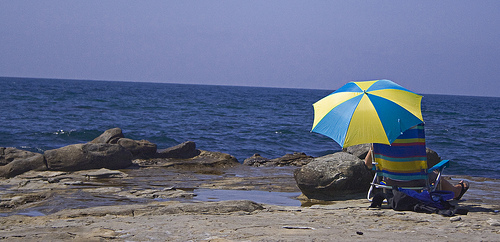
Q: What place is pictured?
A: It is a beach.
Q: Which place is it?
A: It is a beach.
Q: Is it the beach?
A: Yes, it is the beach.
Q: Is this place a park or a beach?
A: It is a beach.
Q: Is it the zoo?
A: No, it is the beach.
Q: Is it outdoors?
A: Yes, it is outdoors.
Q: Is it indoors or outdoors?
A: It is outdoors.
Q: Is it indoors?
A: No, it is outdoors.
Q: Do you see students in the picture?
A: No, there are no students.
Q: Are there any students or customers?
A: No, there are no students or customers.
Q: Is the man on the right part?
A: Yes, the man is on the right of the image.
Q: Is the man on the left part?
A: No, the man is on the right of the image.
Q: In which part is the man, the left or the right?
A: The man is on the right of the image.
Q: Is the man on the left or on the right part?
A: The man is on the right of the image.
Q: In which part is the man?
A: The man is on the right of the image.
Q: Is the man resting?
A: Yes, the man is resting.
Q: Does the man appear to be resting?
A: Yes, the man is resting.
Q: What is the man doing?
A: The man is resting.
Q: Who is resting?
A: The man is resting.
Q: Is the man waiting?
A: No, the man is resting.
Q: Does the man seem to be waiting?
A: No, the man is resting.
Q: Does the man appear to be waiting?
A: No, the man is resting.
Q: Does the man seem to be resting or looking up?
A: The man is resting.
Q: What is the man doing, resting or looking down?
A: The man is resting.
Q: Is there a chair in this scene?
A: Yes, there is a chair.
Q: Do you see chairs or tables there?
A: Yes, there is a chair.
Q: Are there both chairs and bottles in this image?
A: No, there is a chair but no bottles.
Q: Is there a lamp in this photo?
A: No, there are no lamps.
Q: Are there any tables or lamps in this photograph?
A: No, there are no lamps or tables.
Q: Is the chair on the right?
A: Yes, the chair is on the right of the image.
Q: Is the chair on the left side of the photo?
A: No, the chair is on the right of the image.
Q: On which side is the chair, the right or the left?
A: The chair is on the right of the image.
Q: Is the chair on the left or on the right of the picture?
A: The chair is on the right of the image.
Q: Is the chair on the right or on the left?
A: The chair is on the right of the image.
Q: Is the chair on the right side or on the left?
A: The chair is on the right of the image.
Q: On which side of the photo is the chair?
A: The chair is on the right of the image.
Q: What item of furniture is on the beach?
A: The piece of furniture is a chair.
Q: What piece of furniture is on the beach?
A: The piece of furniture is a chair.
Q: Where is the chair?
A: The chair is on the beach.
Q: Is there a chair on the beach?
A: Yes, there is a chair on the beach.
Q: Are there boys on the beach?
A: No, there is a chair on the beach.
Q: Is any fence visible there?
A: No, there are no fences.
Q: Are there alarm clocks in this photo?
A: No, there are no alarm clocks.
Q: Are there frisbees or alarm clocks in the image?
A: No, there are no alarm clocks or frisbees.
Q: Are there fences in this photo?
A: No, there are no fences.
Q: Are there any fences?
A: No, there are no fences.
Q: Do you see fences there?
A: No, there are no fences.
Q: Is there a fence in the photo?
A: No, there are no fences.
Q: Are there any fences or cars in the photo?
A: No, there are no fences or cars.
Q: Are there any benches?
A: No, there are no benches.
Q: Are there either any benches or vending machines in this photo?
A: No, there are no benches or vending machines.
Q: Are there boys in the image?
A: No, there are no boys.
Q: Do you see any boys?
A: No, there are no boys.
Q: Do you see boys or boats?
A: No, there are no boys or boats.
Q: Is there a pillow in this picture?
A: No, there are no pillows.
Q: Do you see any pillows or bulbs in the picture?
A: No, there are no pillows or bulbs.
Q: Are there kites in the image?
A: No, there are no kites.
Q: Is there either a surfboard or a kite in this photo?
A: No, there are no kites or surfboards.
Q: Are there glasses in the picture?
A: No, there are no glasses.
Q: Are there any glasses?
A: No, there are no glasses.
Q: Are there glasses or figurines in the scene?
A: No, there are no glasses or figurines.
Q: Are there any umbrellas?
A: Yes, there is an umbrella.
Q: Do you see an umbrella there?
A: Yes, there is an umbrella.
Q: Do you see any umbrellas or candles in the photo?
A: Yes, there is an umbrella.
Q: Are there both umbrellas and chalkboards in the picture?
A: No, there is an umbrella but no chalkboards.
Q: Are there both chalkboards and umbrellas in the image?
A: No, there is an umbrella but no chalkboards.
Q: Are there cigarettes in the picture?
A: No, there are no cigarettes.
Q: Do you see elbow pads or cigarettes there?
A: No, there are no cigarettes or elbow pads.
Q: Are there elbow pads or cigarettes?
A: No, there are no cigarettes or elbow pads.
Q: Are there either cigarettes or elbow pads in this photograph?
A: No, there are no cigarettes or elbow pads.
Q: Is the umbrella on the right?
A: Yes, the umbrella is on the right of the image.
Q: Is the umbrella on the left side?
A: No, the umbrella is on the right of the image.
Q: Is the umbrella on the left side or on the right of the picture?
A: The umbrella is on the right of the image.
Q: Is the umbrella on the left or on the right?
A: The umbrella is on the right of the image.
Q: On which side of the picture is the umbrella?
A: The umbrella is on the right of the image.